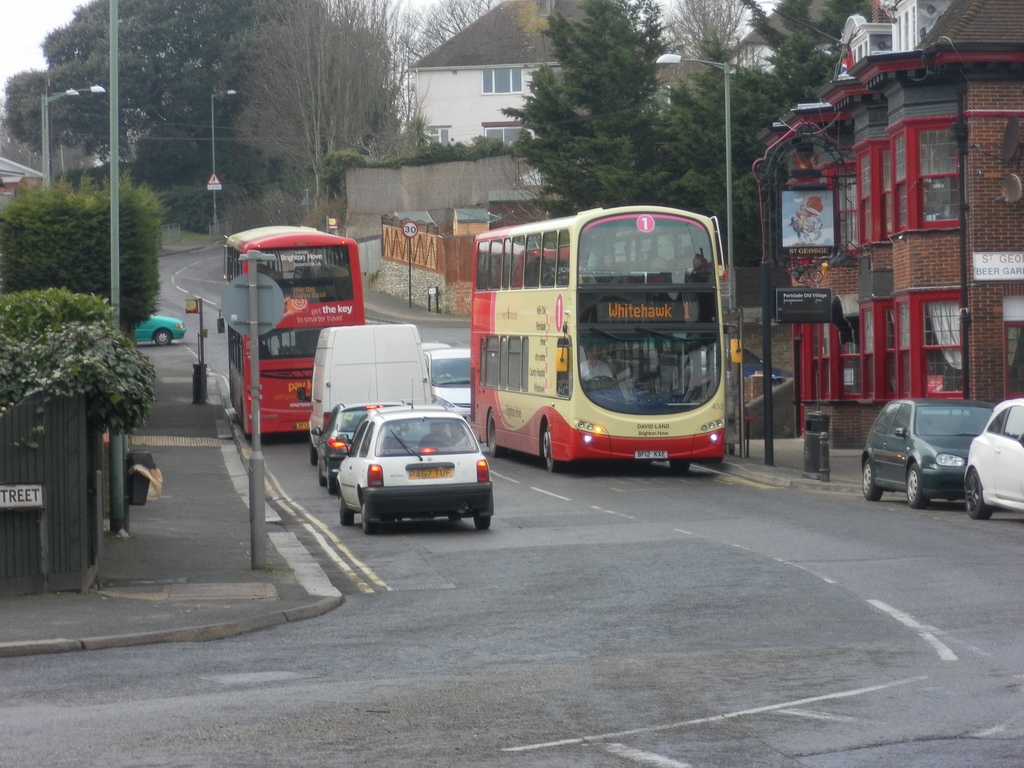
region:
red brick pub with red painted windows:
[751, 40, 1023, 471]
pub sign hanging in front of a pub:
[774, 170, 841, 263]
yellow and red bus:
[461, 199, 743, 481]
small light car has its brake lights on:
[328, 405, 500, 541]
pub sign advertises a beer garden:
[969, 244, 1021, 284]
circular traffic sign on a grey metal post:
[220, 244, 290, 577]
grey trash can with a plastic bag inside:
[116, 443, 171, 516]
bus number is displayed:
[675, 297, 698, 324]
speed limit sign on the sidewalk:
[397, 218, 424, 308]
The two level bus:
[450, 199, 751, 504]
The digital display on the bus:
[597, 292, 680, 324]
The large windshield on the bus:
[571, 205, 724, 425]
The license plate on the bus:
[628, 440, 679, 470]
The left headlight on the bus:
[574, 425, 600, 454]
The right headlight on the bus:
[701, 425, 730, 451]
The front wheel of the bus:
[529, 420, 574, 472]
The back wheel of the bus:
[483, 395, 504, 453]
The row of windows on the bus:
[472, 332, 548, 397]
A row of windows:
[461, 219, 595, 296]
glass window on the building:
[912, 125, 952, 171]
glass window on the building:
[918, 175, 958, 214]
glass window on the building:
[918, 292, 961, 344]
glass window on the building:
[917, 343, 959, 394]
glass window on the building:
[855, 156, 866, 195]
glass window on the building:
[855, 197, 871, 237]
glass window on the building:
[899, 349, 901, 394]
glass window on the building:
[1009, 323, 1017, 390]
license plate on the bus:
[629, 440, 672, 461]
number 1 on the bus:
[629, 209, 658, 236]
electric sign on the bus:
[597, 296, 692, 325]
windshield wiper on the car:
[373, 420, 427, 471]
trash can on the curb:
[796, 401, 831, 466]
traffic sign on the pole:
[201, 259, 288, 337]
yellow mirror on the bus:
[537, 339, 572, 379]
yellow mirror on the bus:
[732, 335, 751, 355]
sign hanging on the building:
[768, 272, 833, 324]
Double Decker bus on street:
[443, 197, 783, 510]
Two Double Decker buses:
[206, 187, 794, 504]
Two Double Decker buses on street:
[194, 168, 770, 513]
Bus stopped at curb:
[206, 205, 377, 462]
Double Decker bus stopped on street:
[201, 212, 388, 454]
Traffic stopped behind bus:
[283, 309, 515, 570]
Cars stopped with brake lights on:
[307, 379, 532, 556]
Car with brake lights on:
[291, 382, 563, 557]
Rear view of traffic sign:
[210, 233, 318, 606]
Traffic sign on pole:
[201, 228, 328, 587]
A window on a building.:
[919, 291, 973, 396]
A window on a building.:
[915, 125, 958, 228]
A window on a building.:
[849, 141, 895, 230]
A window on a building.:
[876, 294, 914, 393]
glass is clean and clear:
[583, 217, 713, 278]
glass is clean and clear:
[581, 336, 714, 407]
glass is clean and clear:
[381, 415, 476, 457]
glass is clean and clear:
[927, 344, 966, 392]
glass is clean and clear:
[897, 134, 910, 182]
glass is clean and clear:
[897, 183, 910, 229]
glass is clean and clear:
[859, 147, 870, 195]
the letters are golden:
[599, 298, 689, 337]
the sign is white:
[7, 485, 66, 521]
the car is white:
[340, 399, 489, 542]